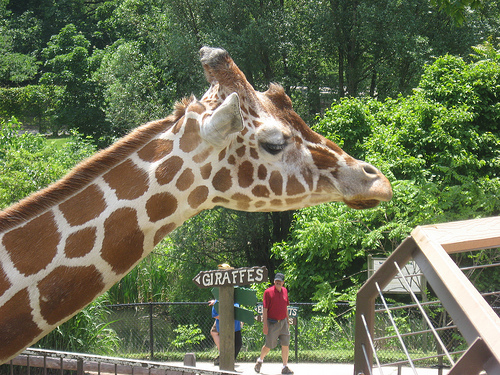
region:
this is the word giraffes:
[174, 248, 298, 312]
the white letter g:
[196, 269, 210, 286]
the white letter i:
[207, 265, 219, 294]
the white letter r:
[211, 268, 228, 293]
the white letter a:
[221, 263, 233, 288]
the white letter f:
[231, 265, 245, 285]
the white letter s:
[253, 265, 270, 285]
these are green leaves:
[434, 130, 474, 195]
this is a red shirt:
[253, 277, 296, 322]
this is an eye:
[251, 116, 291, 166]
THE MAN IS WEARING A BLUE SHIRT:
[206, 297, 247, 340]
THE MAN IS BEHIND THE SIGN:
[190, 256, 263, 373]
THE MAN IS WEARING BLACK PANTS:
[223, 326, 248, 369]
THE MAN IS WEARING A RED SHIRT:
[259, 279, 294, 326]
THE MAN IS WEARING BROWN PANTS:
[257, 313, 296, 355]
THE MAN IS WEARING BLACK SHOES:
[249, 357, 296, 373]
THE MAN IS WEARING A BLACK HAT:
[269, 269, 289, 287]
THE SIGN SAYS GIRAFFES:
[195, 266, 273, 292]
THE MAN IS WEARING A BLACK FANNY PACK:
[266, 312, 276, 327]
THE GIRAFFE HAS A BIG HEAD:
[163, 32, 413, 254]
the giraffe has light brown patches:
[3, 51, 392, 356]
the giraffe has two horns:
[197, 42, 254, 102]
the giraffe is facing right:
[2, 48, 395, 350]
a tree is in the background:
[291, 49, 499, 302]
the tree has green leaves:
[273, 51, 497, 306]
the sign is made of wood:
[193, 265, 265, 290]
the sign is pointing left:
[192, 267, 268, 284]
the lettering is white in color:
[204, 269, 264, 284]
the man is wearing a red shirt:
[263, 284, 290, 318]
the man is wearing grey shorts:
[261, 315, 291, 350]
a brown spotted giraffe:
[0, 42, 399, 367]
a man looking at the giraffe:
[252, 266, 300, 374]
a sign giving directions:
[201, 251, 263, 368]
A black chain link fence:
[54, 293, 497, 368]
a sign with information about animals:
[362, 249, 434, 299]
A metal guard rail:
[349, 210, 499, 374]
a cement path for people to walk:
[7, 340, 484, 373]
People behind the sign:
[207, 264, 242, 366]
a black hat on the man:
[271, 270, 288, 286]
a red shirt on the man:
[260, 285, 293, 329]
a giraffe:
[109, 102, 302, 215]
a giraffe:
[128, 69, 360, 331]